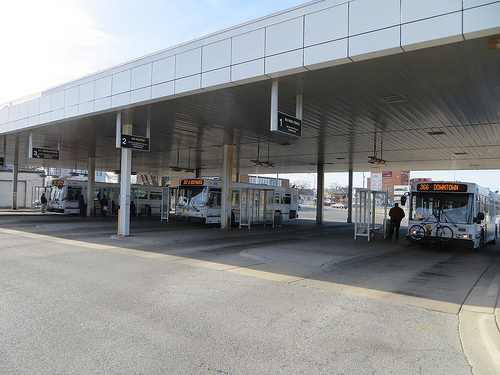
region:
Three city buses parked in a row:
[15, 160, 493, 262]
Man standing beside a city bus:
[379, 180, 446, 267]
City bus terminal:
[5, 0, 498, 245]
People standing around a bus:
[22, 175, 162, 226]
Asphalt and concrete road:
[1, 245, 457, 370]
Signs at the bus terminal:
[5, 105, 321, 168]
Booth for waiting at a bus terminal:
[337, 181, 393, 257]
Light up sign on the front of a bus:
[397, 172, 478, 202]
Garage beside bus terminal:
[0, 137, 52, 233]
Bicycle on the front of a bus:
[404, 196, 478, 264]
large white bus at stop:
[44, 177, 172, 215]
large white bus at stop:
[173, 176, 301, 226]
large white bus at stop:
[406, 175, 498, 250]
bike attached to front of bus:
[407, 214, 454, 241]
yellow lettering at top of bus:
[417, 182, 460, 192]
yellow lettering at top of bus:
[182, 177, 205, 187]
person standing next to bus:
[385, 200, 406, 240]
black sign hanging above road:
[271, 109, 303, 138]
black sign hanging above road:
[118, 133, 150, 152]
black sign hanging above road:
[28, 145, 61, 162]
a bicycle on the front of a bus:
[408, 210, 458, 247]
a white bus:
[408, 167, 498, 259]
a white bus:
[178, 172, 301, 227]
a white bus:
[45, 177, 173, 220]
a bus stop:
[353, 182, 388, 245]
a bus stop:
[242, 187, 283, 229]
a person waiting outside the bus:
[381, 195, 404, 245]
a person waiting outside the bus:
[36, 188, 51, 210]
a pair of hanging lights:
[356, 127, 396, 177]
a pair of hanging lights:
[243, 150, 278, 174]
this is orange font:
[407, 174, 478, 204]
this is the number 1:
[276, 113, 287, 128]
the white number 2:
[116, 132, 130, 146]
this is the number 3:
[28, 149, 42, 160]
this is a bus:
[391, 154, 498, 266]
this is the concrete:
[82, 277, 175, 333]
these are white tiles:
[117, 68, 162, 94]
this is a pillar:
[104, 109, 149, 264]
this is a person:
[377, 200, 416, 247]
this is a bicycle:
[399, 202, 472, 259]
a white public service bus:
[405, 174, 495, 253]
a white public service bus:
[165, 174, 300, 227]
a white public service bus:
[39, 174, 173, 216]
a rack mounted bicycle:
[405, 216, 455, 247]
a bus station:
[2, 8, 493, 293]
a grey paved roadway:
[1, 211, 497, 373]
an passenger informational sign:
[262, 108, 307, 141]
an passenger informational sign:
[112, 129, 152, 154]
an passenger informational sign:
[27, 144, 64, 162]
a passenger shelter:
[230, 182, 281, 235]